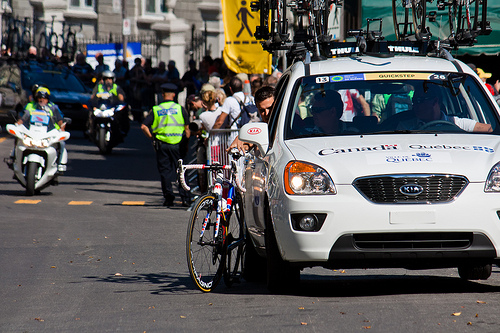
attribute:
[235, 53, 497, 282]
car — white, kia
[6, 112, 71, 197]
motorcycle — white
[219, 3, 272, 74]
sign — yellow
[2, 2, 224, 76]
building — grey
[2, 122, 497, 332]
road — black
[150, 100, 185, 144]
vest — neon green, green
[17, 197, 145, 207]
stripe — yellow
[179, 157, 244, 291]
bike — white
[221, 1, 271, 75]
flag — yellow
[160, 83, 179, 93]
cap — blue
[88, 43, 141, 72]
sign — white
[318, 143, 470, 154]
letters — canada que bee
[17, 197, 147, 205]
lines — yellow